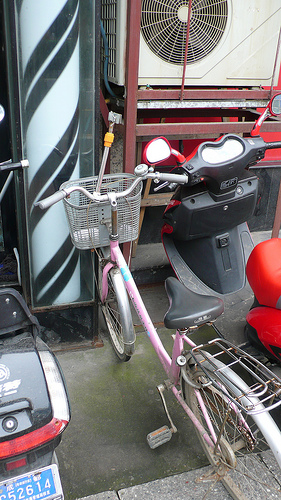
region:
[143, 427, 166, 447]
part of a pedal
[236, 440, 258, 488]
inner part of a wheel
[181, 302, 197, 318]
part of a black seat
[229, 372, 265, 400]
part of the rare seat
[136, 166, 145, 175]
part of a bell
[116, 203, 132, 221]
part of a basket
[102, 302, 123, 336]
part of a front wheel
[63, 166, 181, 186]
part of a steering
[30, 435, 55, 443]
part of an indicator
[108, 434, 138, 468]
part of the surface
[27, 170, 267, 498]
girls bicycle with basket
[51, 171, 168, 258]
bicycle basket on girls bike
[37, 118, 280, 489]
bicycle and scooter parked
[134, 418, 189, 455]
bicycle pedal on ground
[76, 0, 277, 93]
air conditioning unit on metal stand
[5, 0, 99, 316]
white pole with black ribbon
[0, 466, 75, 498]
scooter number plate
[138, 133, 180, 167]
mirror on scooter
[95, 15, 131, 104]
pipe on air conditioner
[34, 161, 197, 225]
bicycle handlebars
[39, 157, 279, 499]
There's a girl's bike between a car and moped.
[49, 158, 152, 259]
There's a basket on the bike.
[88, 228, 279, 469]
The girl's bike is pink.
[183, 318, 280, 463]
Fenders on the bike are silver.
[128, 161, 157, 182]
There's a bell on the handlebars.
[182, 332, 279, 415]
There's a book rack above back fender.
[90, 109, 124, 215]
The kickstand is in the basket.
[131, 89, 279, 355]
The moped is red.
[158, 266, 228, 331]
The bike has a black seat.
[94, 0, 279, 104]
There's an air conditioner in front of moped.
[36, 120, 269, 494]
the bike is parked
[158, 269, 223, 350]
the seat is black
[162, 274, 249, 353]
the seat is made of plastic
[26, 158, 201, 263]
the bike has basket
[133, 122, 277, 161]
the mirror holder is red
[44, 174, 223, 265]
the basket is gray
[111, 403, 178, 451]
the pedal is gray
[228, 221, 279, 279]
the seat is red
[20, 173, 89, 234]
the handle is gray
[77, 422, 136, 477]
the floor is gray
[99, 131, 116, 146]
a yellow plastic slip on a tube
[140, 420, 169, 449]
a gray bike pedal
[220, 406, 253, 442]
a rusted chain on bike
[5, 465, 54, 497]
a blue and whit license plate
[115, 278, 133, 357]
a silver fender covering a tire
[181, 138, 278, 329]
red moped parked next to a bike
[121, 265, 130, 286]
a ble logo on the bike's bar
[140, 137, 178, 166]
a side view mirror on the moped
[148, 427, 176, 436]
a yellow reflector on a bike pedal